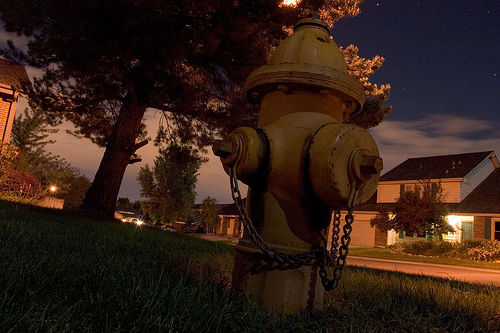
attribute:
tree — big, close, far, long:
[77, 40, 180, 245]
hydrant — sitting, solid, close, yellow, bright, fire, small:
[227, 38, 362, 321]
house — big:
[391, 148, 499, 256]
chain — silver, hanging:
[284, 168, 376, 292]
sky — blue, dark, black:
[391, 15, 489, 104]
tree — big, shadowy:
[0, 2, 375, 323]